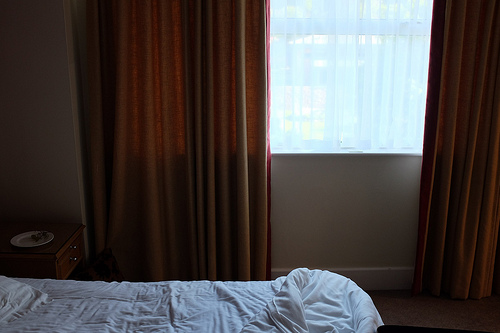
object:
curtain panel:
[420, 1, 498, 304]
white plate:
[8, 226, 61, 249]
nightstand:
[3, 211, 86, 278]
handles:
[32, 249, 138, 290]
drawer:
[63, 230, 176, 280]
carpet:
[380, 287, 500, 323]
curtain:
[435, 130, 483, 255]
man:
[283, 5, 427, 156]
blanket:
[10, 258, 417, 331]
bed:
[1, 265, 387, 331]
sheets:
[18, 270, 373, 331]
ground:
[333, 171, 350, 200]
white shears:
[263, 0, 433, 162]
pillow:
[0, 271, 57, 327]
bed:
[1, 257, 386, 330]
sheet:
[245, 295, 315, 330]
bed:
[31, 270, 251, 329]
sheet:
[243, 266, 383, 329]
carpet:
[404, 303, 457, 319]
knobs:
[71, 239, 81, 264]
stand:
[9, 200, 92, 277]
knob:
[69, 252, 88, 266]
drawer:
[56, 242, 106, 277]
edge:
[375, 324, 496, 332]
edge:
[2, 270, 322, 287]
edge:
[3, 247, 61, 263]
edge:
[55, 223, 91, 257]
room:
[3, 2, 499, 330]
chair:
[372, 321, 489, 330]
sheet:
[248, 263, 387, 331]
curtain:
[25, 0, 273, 272]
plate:
[6, 225, 56, 250]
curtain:
[423, 1, 496, 299]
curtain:
[80, 3, 271, 276]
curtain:
[268, 2, 428, 155]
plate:
[11, 222, 49, 247]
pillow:
[0, 266, 47, 332]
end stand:
[1, 220, 91, 284]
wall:
[255, 174, 422, 217]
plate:
[10, 227, 68, 262]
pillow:
[0, 265, 53, 327]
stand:
[0, 215, 105, 278]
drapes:
[73, 3, 273, 284]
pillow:
[274, 263, 388, 332]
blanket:
[2, 270, 384, 332]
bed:
[0, 262, 382, 327]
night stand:
[2, 212, 98, 280]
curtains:
[71, 0, 486, 304]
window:
[267, 2, 430, 159]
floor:
[367, 284, 485, 331]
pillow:
[70, 241, 128, 276]